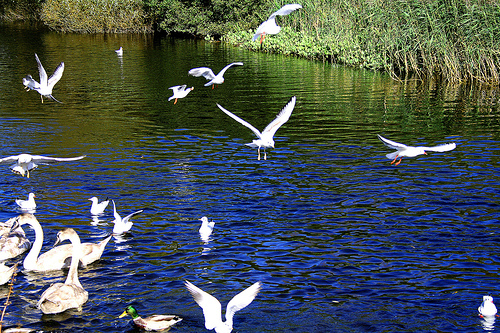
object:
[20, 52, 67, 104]
bird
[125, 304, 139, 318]
face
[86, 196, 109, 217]
bird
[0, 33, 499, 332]
water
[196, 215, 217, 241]
bird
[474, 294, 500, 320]
bird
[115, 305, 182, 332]
bird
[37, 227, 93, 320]
bird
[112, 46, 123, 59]
bird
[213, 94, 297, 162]
bird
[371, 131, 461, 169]
birds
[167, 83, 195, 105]
bird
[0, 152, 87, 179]
bird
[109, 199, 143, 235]
bird